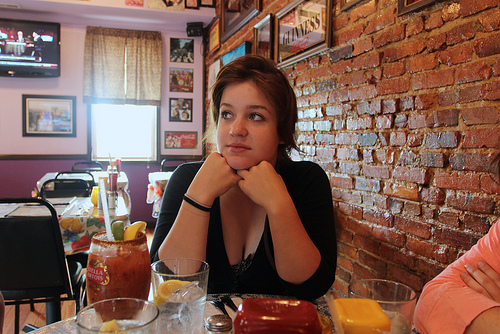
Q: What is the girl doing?
A: Waiting to be served.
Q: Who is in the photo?
A: A lady.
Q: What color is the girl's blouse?
A: Black.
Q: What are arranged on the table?
A: Glasses.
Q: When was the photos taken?
A: Daytime.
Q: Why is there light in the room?
A: The sun is there.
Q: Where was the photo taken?
A: At lunch drinking bloody Mary's.